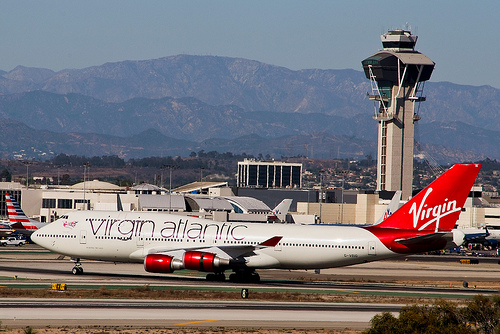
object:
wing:
[134, 235, 283, 273]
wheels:
[227, 264, 260, 283]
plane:
[26, 163, 492, 288]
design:
[1, 192, 40, 231]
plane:
[1, 191, 49, 235]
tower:
[360, 18, 437, 223]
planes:
[14, 160, 482, 282]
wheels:
[71, 264, 84, 275]